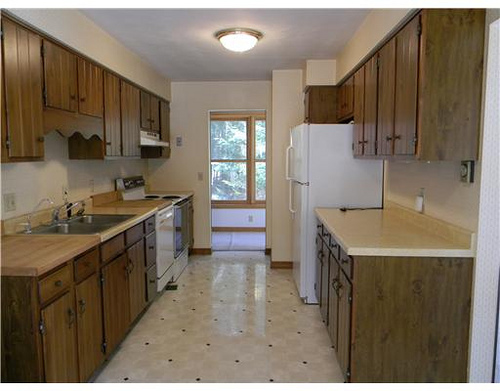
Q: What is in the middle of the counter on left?
A: Sink.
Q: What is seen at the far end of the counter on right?
A: Refrigerator.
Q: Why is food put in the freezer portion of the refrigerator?
A: To keep frozen.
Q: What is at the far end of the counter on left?
A: Stove.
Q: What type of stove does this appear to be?
A: Electric.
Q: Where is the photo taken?
A: Kitchen.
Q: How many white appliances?
A: 3.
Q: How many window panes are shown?
A: 4.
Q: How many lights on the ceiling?
A: 1.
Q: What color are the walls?
A: White.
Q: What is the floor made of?
A: Linoleum.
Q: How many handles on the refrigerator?
A: 2.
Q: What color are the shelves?
A: Brown.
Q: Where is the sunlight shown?
A: Windows.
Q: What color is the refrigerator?
A: White.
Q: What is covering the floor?
A: Tile.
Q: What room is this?
A: Kitchen.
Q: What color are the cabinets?
A: Brown.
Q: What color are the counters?
A: Tan.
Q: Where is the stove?
A: In the back left.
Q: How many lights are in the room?
A: One.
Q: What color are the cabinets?
A: Brown.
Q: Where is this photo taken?
A: In a kitchen.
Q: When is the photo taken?
A: The daytime.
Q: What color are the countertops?
A: White.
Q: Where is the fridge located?
A: On the right side.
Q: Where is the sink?
A: On the left side.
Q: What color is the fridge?
A: White.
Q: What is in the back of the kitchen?
A: A window.